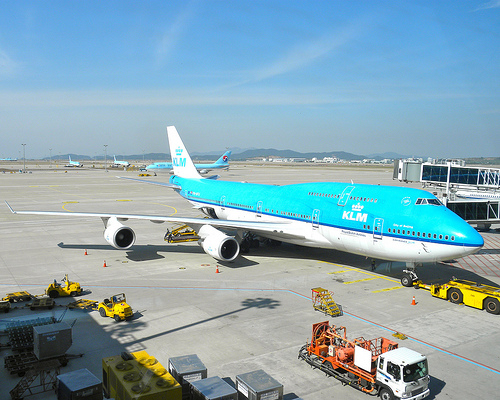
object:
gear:
[401, 273, 413, 286]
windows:
[362, 224, 457, 242]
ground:
[175, 285, 232, 336]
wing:
[3, 200, 304, 240]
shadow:
[122, 297, 282, 353]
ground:
[142, 275, 202, 308]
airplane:
[64, 154, 84, 168]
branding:
[341, 203, 368, 223]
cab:
[296, 321, 435, 400]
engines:
[103, 217, 240, 263]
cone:
[410, 295, 416, 305]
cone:
[215, 265, 220, 274]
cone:
[103, 259, 107, 267]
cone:
[84, 249, 88, 254]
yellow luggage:
[0, 275, 142, 323]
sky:
[0, 0, 499, 171]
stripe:
[175, 191, 481, 248]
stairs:
[311, 287, 341, 317]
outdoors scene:
[0, 0, 498, 396]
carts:
[428, 275, 500, 316]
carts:
[66, 293, 134, 323]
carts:
[0, 274, 83, 316]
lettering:
[341, 202, 368, 223]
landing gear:
[400, 262, 419, 288]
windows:
[415, 197, 445, 207]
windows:
[304, 189, 380, 204]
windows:
[249, 204, 318, 226]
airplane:
[144, 150, 232, 175]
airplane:
[111, 155, 131, 171]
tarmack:
[3, 161, 499, 399]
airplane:
[2, 125, 483, 288]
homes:
[246, 155, 463, 166]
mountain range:
[39, 146, 428, 161]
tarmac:
[0, 157, 499, 399]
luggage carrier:
[410, 275, 500, 316]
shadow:
[55, 242, 205, 263]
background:
[0, 0, 499, 203]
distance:
[0, 123, 500, 185]